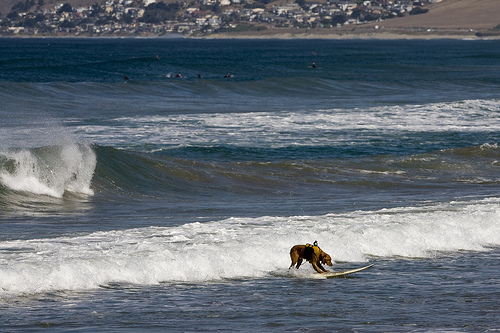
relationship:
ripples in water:
[17, 193, 499, 284] [0, 37, 495, 332]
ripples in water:
[371, 263, 492, 331] [0, 37, 495, 332]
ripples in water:
[335, 280, 487, 330] [0, 37, 495, 332]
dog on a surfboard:
[284, 238, 334, 275] [273, 261, 375, 283]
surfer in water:
[309, 57, 320, 71] [0, 37, 495, 332]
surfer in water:
[220, 69, 232, 79] [0, 37, 495, 332]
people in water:
[176, 73, 184, 78] [0, 37, 495, 332]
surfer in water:
[196, 70, 203, 80] [0, 37, 495, 332]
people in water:
[122, 75, 129, 84] [0, 37, 495, 332]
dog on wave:
[287, 243, 332, 273] [4, 192, 499, 299]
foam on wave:
[0, 196, 499, 311] [1, 142, 494, 303]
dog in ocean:
[287, 243, 332, 273] [4, 38, 498, 321]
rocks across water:
[6, 1, 433, 33] [0, 37, 495, 332]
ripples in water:
[335, 157, 397, 179] [0, 37, 495, 332]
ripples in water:
[50, 288, 125, 323] [0, 37, 495, 332]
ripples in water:
[2, 91, 419, 323] [36, 195, 141, 289]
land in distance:
[343, 0, 498, 30] [1, 0, 498, 35]